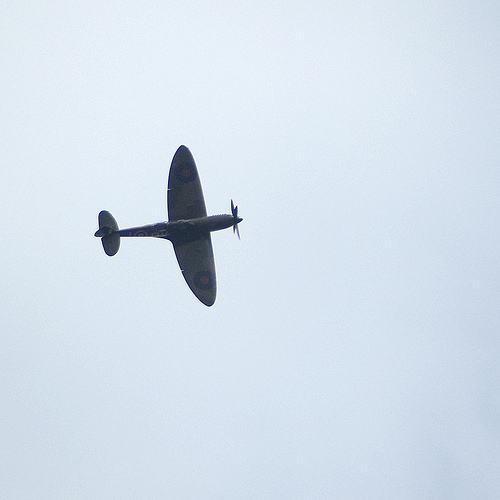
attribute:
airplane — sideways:
[94, 143, 242, 306]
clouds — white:
[26, 31, 111, 95]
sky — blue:
[256, 1, 498, 498]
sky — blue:
[298, 72, 457, 217]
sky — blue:
[108, 385, 183, 452]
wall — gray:
[169, 108, 254, 151]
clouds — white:
[244, 33, 424, 157]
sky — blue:
[4, 2, 499, 499]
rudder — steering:
[88, 224, 101, 245]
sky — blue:
[285, 89, 473, 289]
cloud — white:
[288, 337, 417, 436]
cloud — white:
[286, 320, 448, 465]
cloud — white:
[336, 278, 448, 419]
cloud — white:
[180, 419, 321, 463]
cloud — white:
[274, 115, 378, 165]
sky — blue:
[294, 150, 395, 250]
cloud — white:
[288, 327, 417, 424]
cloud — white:
[320, 197, 404, 258]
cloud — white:
[75, 364, 209, 454]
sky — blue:
[267, 127, 485, 418]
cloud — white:
[344, 361, 457, 452]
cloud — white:
[64, 332, 174, 411]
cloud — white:
[303, 245, 415, 307]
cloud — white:
[315, 247, 395, 311]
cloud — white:
[338, 297, 424, 347]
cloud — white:
[333, 404, 385, 456]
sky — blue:
[238, 50, 431, 492]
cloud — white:
[114, 390, 224, 457]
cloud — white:
[345, 411, 401, 481]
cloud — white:
[192, 432, 292, 471]